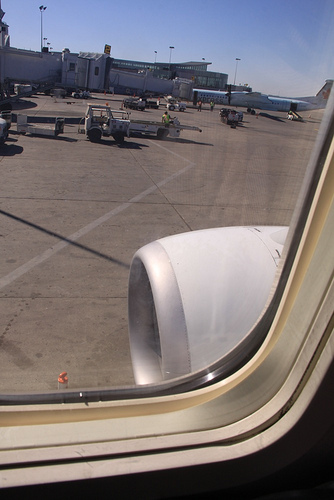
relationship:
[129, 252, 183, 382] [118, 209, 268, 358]
frame on engine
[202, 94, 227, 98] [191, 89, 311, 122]
windows on plane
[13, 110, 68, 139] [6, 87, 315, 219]
cart on road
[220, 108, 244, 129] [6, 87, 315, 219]
vehicle on road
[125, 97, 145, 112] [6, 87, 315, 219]
cart on road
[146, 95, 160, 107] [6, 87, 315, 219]
cart on road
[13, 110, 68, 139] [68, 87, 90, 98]
cart behind vehicle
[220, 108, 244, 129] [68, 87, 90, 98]
vehicle behind vehicle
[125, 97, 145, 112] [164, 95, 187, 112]
cart behind vehicle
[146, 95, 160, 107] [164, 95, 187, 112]
cart behind vehicle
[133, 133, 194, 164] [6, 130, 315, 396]
white line on road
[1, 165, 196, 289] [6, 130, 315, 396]
white line on road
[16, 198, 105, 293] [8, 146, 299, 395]
black line on road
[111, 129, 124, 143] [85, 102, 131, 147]
wheels on vehicle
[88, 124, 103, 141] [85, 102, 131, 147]
wheels on vehicle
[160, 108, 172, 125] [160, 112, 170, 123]
person wearing vest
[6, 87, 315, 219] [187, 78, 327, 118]
road connected to plane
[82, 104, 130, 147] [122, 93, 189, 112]
jeep and carts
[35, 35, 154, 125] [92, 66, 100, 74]
building with windows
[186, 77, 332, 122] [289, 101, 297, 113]
airplane with open door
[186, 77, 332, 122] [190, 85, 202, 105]
airplane with open doors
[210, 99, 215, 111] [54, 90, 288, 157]
workers standing on runway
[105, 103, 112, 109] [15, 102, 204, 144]
light on top vehicle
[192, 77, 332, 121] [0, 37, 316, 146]
airplane at airport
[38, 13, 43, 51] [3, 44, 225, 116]
pole on top of building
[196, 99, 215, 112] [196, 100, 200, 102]
workers walking around in vest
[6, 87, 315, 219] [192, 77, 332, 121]
road to connect to airplane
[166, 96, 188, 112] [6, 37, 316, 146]
carts at airport